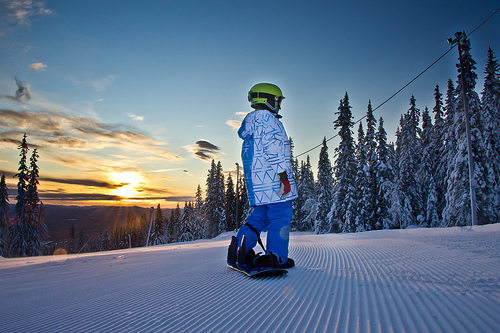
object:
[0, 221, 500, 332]
snow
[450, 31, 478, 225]
light post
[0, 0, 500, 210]
sky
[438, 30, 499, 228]
paisley print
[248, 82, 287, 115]
yellow helmet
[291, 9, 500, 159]
cable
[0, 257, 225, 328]
lines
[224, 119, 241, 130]
clouds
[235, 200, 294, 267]
pants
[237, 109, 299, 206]
jacket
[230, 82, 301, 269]
person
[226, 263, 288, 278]
snowboard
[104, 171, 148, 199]
sun